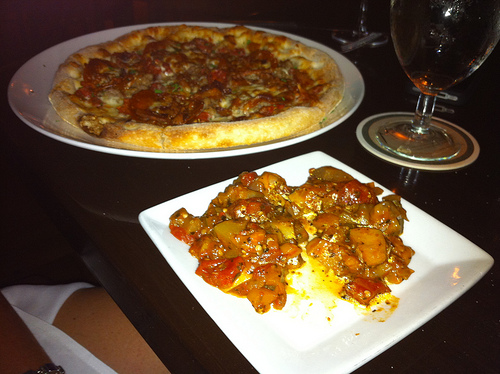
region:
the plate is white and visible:
[60, 84, 472, 360]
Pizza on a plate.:
[48, 23, 343, 150]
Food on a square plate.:
[165, 162, 418, 322]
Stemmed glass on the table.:
[366, 1, 491, 166]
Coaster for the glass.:
[351, 106, 481, 171]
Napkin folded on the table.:
[0, 277, 175, 368]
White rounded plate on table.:
[5, 17, 370, 153]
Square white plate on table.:
[130, 146, 491, 368]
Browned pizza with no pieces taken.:
[46, 22, 348, 149]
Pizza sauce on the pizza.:
[80, 33, 322, 126]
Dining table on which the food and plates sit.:
[3, 5, 499, 368]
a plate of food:
[136, 151, 497, 369]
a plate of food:
[2, 22, 365, 154]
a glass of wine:
[361, 0, 499, 177]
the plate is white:
[130, 146, 497, 370]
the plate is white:
[6, 15, 378, 152]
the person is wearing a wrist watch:
[23, 358, 85, 372]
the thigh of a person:
[61, 277, 180, 372]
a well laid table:
[0, 1, 489, 370]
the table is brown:
[0, 2, 495, 367]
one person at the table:
[3, 0, 495, 370]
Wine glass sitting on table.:
[377, 58, 474, 190]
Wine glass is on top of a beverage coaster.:
[371, 92, 461, 202]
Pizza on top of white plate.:
[36, 74, 193, 169]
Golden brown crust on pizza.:
[142, 124, 221, 165]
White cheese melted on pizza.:
[126, 85, 218, 143]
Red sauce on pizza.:
[119, 89, 209, 124]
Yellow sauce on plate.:
[316, 258, 344, 300]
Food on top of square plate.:
[162, 167, 333, 366]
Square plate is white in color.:
[199, 179, 344, 299]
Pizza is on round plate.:
[27, 70, 289, 177]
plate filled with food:
[131, 135, 452, 320]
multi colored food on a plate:
[205, 192, 320, 264]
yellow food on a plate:
[207, 157, 355, 275]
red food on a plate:
[122, 204, 319, 301]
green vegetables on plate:
[231, 210, 281, 250]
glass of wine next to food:
[377, 5, 468, 190]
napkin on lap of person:
[17, 251, 94, 322]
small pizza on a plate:
[8, 31, 305, 178]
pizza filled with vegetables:
[2, 44, 276, 148]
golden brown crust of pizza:
[175, 115, 292, 155]